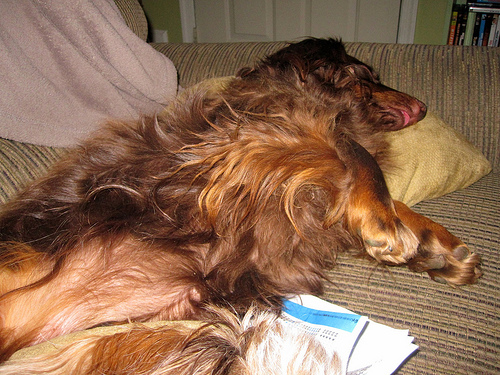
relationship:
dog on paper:
[10, 22, 489, 370] [287, 301, 419, 373]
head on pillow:
[262, 25, 432, 141] [405, 139, 452, 184]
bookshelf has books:
[445, 1, 499, 52] [456, 18, 492, 39]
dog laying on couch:
[10, 22, 489, 370] [409, 56, 469, 90]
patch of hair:
[226, 106, 271, 144] [247, 77, 291, 114]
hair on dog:
[247, 77, 291, 114] [10, 22, 489, 370]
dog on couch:
[10, 22, 489, 370] [409, 56, 469, 90]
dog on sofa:
[10, 22, 489, 370] [168, 46, 225, 68]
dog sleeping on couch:
[10, 22, 489, 370] [409, 56, 469, 90]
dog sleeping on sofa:
[10, 22, 489, 370] [168, 46, 225, 68]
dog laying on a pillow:
[10, 22, 489, 370] [405, 139, 452, 184]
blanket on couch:
[64, 37, 121, 80] [409, 56, 469, 90]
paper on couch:
[287, 301, 348, 324] [409, 56, 469, 90]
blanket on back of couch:
[64, 37, 121, 80] [409, 56, 469, 90]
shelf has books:
[445, 1, 499, 52] [456, 18, 492, 39]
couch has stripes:
[409, 56, 469, 90] [8, 146, 30, 170]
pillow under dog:
[405, 139, 452, 184] [10, 22, 489, 370]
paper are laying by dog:
[287, 301, 419, 373] [10, 22, 489, 370]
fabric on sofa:
[129, 9, 142, 22] [168, 46, 225, 68]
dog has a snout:
[10, 22, 489, 370] [408, 91, 430, 130]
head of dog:
[262, 25, 432, 141] [10, 22, 489, 370]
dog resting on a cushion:
[10, 22, 489, 370] [426, 125, 458, 146]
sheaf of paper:
[244, 308, 272, 327] [287, 301, 419, 373]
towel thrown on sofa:
[16, 10, 120, 113] [168, 46, 225, 68]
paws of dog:
[379, 242, 442, 269] [10, 22, 489, 370]